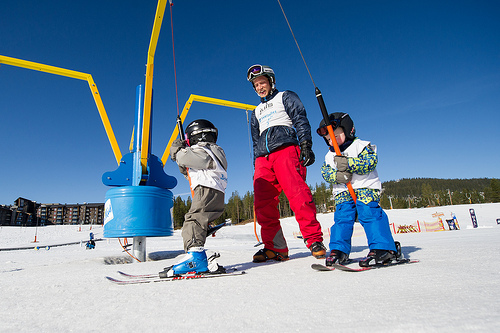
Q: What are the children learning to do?
A: Ski.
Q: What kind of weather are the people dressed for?
A: Cold.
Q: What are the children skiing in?
A: Snow.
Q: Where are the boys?
A: Snow ride.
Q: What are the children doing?
A: Skiing.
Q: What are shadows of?
A: Skiers.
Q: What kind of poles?
A: Ski poles.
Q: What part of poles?
A: Handles.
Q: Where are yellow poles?
A: Sticking out of base.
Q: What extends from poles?
A: Wires.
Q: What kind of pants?
A: Snowpants.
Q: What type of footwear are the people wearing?
A: Boots.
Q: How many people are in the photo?
A: Three.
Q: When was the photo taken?
A: During the day.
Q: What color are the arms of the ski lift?
A: Yellow.